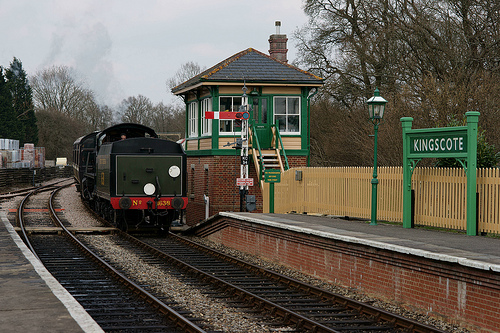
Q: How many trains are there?
A: 1.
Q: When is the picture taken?
A: Daytime.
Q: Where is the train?
A: On the tracks.